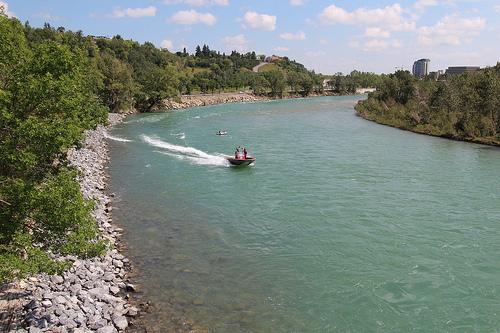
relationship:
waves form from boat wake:
[100, 128, 134, 149] [173, 147, 231, 171]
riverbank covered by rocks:
[44, 115, 123, 332] [52, 283, 115, 322]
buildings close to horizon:
[412, 58, 430, 80] [310, 72, 494, 81]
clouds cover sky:
[316, 9, 478, 54] [5, 1, 497, 61]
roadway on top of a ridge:
[175, 87, 318, 96] [173, 94, 263, 106]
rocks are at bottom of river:
[124, 218, 267, 332] [125, 96, 485, 331]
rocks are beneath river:
[124, 218, 267, 332] [125, 96, 485, 331]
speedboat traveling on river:
[225, 148, 257, 170] [125, 96, 485, 331]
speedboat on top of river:
[225, 148, 257, 170] [125, 96, 485, 331]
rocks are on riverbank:
[52, 283, 115, 322] [44, 115, 123, 332]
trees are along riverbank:
[0, 33, 98, 139] [44, 115, 123, 332]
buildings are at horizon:
[410, 61, 477, 81] [310, 72, 494, 81]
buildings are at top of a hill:
[248, 54, 287, 65] [237, 53, 306, 89]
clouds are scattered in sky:
[316, 9, 478, 54] [5, 1, 497, 61]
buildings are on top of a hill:
[248, 54, 287, 65] [237, 53, 306, 89]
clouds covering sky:
[316, 9, 478, 54] [5, 1, 497, 61]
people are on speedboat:
[234, 147, 246, 156] [225, 148, 257, 170]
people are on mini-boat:
[219, 130, 223, 133] [216, 131, 229, 139]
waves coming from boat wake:
[100, 128, 134, 149] [173, 147, 231, 171]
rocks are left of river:
[52, 283, 115, 322] [125, 96, 485, 331]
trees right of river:
[375, 90, 497, 132] [125, 96, 485, 331]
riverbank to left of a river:
[44, 115, 123, 332] [125, 96, 485, 331]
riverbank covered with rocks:
[44, 115, 123, 332] [52, 283, 115, 322]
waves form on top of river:
[100, 128, 134, 149] [125, 96, 485, 331]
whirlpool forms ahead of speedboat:
[363, 258, 477, 318] [225, 148, 257, 170]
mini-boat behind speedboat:
[216, 131, 229, 139] [225, 148, 257, 170]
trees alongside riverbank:
[0, 33, 98, 139] [44, 115, 123, 332]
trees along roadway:
[137, 64, 275, 86] [175, 87, 318, 96]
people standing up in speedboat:
[234, 147, 246, 156] [225, 148, 257, 170]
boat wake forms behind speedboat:
[173, 147, 231, 171] [225, 148, 257, 170]